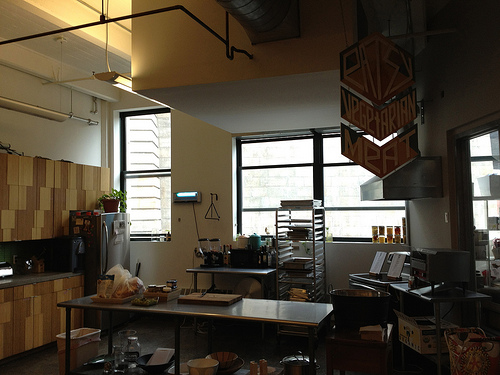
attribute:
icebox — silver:
[66, 209, 139, 339]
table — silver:
[48, 283, 345, 373]